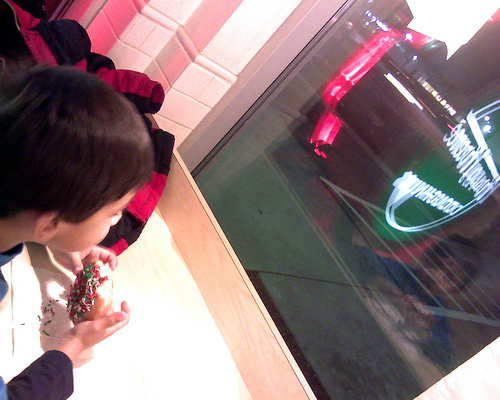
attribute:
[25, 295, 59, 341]
sprinkles — green red, white, red white, green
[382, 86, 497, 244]
logo — green, white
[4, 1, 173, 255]
jacket — red, black, pink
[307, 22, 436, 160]
red light — lighted up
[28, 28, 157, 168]
coat — black, red